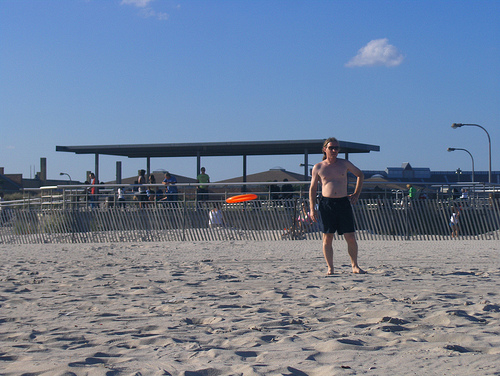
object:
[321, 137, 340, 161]
hair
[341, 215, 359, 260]
leg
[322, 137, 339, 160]
head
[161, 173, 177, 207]
man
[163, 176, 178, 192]
shirt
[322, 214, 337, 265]
leg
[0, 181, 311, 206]
railing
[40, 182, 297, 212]
boardwalk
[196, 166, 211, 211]
man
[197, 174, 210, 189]
shirt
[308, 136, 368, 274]
man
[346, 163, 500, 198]
building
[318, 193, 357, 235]
shorts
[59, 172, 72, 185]
pole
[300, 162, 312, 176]
pole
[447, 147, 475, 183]
pole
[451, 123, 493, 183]
pole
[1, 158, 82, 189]
building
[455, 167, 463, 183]
pole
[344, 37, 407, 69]
cloud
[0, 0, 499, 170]
sky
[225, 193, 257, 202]
freesbee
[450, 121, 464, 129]
lamp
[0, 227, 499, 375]
beach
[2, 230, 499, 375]
sand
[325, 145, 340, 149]
sunglasses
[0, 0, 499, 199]
air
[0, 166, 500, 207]
background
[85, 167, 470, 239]
crowd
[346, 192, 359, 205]
hand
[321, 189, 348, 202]
waist